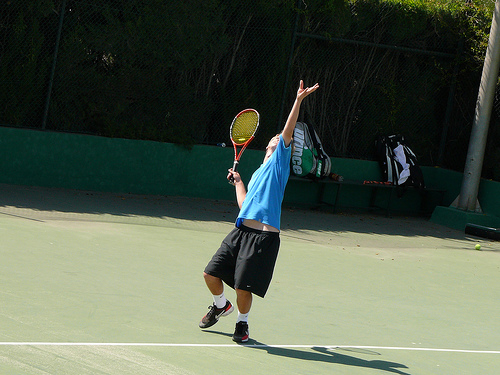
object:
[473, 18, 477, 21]
leaves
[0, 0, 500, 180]
trees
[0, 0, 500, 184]
fence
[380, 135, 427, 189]
backpack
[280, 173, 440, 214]
bench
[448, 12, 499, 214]
pole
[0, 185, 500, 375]
ground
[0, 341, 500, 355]
lines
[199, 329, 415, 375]
shadow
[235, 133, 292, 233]
shirt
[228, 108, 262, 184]
racket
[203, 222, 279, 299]
shorts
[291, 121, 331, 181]
bags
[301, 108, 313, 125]
equipment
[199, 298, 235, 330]
tennis shoes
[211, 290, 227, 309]
socks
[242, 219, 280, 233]
midriff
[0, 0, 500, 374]
court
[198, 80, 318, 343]
player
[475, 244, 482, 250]
ball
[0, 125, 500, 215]
wall